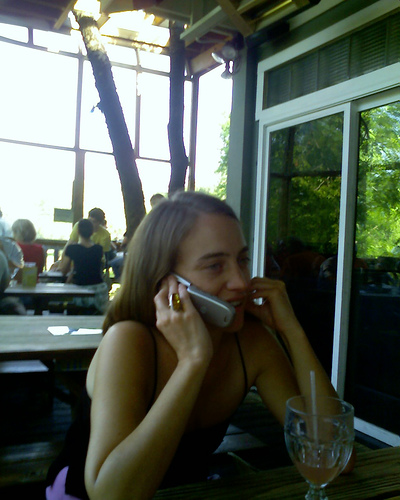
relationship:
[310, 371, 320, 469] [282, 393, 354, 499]
straw in glass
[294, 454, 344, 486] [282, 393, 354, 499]
liquid in glass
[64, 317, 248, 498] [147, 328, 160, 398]
shirt has straps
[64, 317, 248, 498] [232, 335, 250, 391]
shirt has straps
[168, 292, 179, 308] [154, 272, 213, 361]
ring on hand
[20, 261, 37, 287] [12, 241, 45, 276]
container has shirt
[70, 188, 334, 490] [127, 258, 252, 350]
girl talking on cellphone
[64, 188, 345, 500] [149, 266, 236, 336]
girl holding cell phone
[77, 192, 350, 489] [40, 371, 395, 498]
lady sitting at table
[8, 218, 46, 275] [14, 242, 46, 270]
person wearing shirt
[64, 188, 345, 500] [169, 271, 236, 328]
girl talking on cell phone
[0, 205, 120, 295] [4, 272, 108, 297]
people sitting at table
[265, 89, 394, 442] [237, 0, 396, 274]
door on building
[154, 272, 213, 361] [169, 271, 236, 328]
hand on cell phone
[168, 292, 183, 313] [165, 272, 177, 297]
ring on finger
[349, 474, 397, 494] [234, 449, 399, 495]
grain on table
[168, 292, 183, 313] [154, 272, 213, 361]
ring on hand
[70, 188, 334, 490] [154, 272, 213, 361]
girl has hand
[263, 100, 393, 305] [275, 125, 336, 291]
reflection on windows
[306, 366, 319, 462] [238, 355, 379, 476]
straw on glass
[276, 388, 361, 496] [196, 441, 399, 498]
glass on table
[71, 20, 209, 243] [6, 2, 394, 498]
tree in building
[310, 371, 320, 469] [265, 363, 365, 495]
straw in glass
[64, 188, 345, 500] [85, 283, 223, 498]
girl has arm